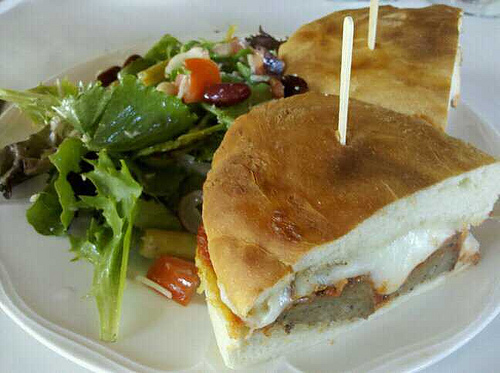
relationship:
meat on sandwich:
[301, 269, 433, 314] [184, 53, 499, 362]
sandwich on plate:
[184, 53, 499, 362] [6, 11, 499, 369]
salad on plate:
[35, 74, 196, 240] [6, 11, 499, 369]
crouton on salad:
[166, 19, 261, 109] [35, 74, 196, 240]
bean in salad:
[174, 79, 244, 114] [35, 74, 196, 240]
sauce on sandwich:
[343, 260, 394, 319] [184, 53, 499, 362]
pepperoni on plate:
[160, 48, 247, 131] [6, 11, 499, 369]